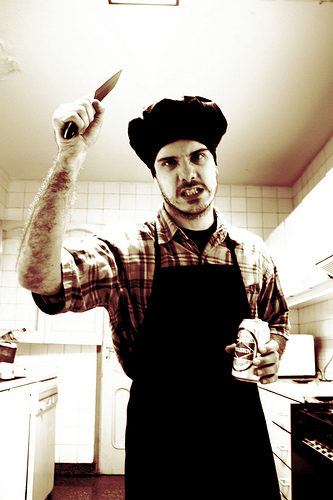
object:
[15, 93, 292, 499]
man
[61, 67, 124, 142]
knife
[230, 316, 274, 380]
can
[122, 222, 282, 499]
apron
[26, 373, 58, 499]
dishwasher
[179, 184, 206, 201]
mouth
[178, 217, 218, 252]
t-shirt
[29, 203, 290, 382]
shirt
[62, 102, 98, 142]
handle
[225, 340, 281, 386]
hand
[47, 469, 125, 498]
floor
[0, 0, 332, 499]
kitchen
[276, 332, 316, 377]
microwave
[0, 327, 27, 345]
bottle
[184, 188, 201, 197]
teeth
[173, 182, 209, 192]
mustache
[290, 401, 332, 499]
stove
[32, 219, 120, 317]
sleeve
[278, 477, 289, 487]
handles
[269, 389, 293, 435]
drawers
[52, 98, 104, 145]
hand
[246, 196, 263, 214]
tiles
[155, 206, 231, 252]
collar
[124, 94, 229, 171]
chef hat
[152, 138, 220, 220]
head